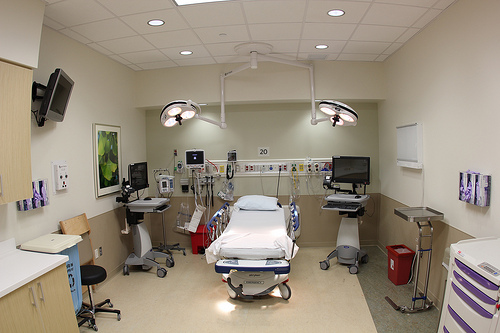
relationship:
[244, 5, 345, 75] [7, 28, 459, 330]
ceiling in room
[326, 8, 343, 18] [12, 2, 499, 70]
lighting on ceiling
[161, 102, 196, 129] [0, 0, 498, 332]
lamps on hospital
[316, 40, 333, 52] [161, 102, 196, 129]
bulbs are in lamps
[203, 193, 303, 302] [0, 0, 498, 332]
bed in hospital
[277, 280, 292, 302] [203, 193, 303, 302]
wheel of a bed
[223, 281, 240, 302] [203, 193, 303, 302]
wheel of a bed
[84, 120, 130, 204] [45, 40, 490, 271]
picture on wall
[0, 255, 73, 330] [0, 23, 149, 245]
cabinet near wall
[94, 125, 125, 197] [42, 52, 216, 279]
picture on wall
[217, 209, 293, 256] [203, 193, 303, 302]
white sheet on bed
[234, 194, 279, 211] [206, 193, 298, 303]
pillow on hospital bed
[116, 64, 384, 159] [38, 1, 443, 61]
lamps on ceiling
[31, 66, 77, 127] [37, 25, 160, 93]
tv mounted on wall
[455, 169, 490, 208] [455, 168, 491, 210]
boxes of gloves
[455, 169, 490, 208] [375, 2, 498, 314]
boxes on wall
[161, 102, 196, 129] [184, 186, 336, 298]
lamps over bed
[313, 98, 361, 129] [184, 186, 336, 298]
light over bed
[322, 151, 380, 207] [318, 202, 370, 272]
computer on rolling stand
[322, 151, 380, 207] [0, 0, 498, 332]
computer in hospital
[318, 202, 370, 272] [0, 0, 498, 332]
stand in hospital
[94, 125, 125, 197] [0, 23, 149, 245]
picture on wall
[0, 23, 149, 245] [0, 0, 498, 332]
wall in hospital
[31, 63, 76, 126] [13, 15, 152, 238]
tv mounted on wall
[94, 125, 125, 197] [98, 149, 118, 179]
picture of leaf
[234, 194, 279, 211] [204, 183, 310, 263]
pillow on hospital bed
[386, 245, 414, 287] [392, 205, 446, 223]
can next to silver tray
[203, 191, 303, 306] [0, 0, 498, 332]
bed in hospital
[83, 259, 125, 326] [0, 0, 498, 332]
stool in hospital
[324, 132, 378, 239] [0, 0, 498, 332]
computer in hospital